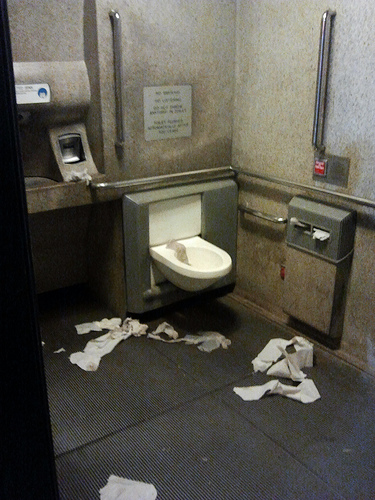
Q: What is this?
A: A bathroom.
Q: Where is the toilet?
A: On the wall.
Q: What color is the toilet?
A: White.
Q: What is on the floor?
A: Trash.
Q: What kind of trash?
A: Toilet paper.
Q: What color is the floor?
A: Gray.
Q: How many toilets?
A: One.